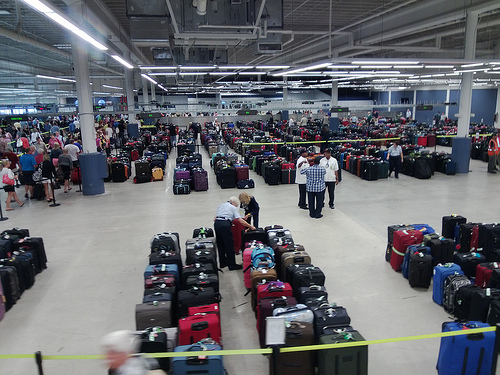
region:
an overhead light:
[108, 51, 133, 70]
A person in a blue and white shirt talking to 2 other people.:
[300, 155, 325, 216]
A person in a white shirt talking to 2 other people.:
[317, 148, 338, 208]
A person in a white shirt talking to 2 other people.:
[293, 147, 315, 209]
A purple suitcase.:
[192, 170, 209, 192]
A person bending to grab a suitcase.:
[213, 196, 255, 268]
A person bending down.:
[238, 192, 259, 228]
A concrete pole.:
[66, 1, 104, 195]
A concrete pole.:
[450, 12, 479, 173]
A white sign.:
[262, 315, 287, 374]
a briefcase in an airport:
[318, 324, 365, 374]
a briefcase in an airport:
[268, 318, 317, 368]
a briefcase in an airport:
[314, 302, 350, 324]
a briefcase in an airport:
[173, 344, 220, 372]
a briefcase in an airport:
[176, 310, 222, 357]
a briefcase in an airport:
[181, 284, 213, 304]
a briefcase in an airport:
[134, 297, 176, 332]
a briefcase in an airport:
[145, 291, 175, 302]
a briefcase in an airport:
[143, 260, 182, 277]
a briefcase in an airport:
[188, 269, 217, 283]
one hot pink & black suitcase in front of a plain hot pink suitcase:
[173, 298, 225, 347]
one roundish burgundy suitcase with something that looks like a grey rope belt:
[387, 228, 423, 272]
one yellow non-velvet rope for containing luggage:
[0, 317, 499, 374]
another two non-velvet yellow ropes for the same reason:
[237, 128, 494, 149]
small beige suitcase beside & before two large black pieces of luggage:
[133, 154, 166, 189]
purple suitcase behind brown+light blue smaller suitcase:
[170, 166, 195, 199]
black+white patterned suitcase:
[436, 270, 474, 319]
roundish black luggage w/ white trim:
[445, 283, 498, 327]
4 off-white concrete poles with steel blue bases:
[65, 1, 480, 198]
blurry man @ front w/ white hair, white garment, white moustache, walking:
[92, 324, 171, 374]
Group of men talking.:
[290, 143, 345, 216]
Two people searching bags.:
[205, 186, 271, 266]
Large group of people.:
[0, 107, 135, 214]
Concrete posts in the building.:
[58, 6, 497, 193]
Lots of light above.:
[13, 1, 497, 116]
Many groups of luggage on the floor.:
[5, 111, 496, 370]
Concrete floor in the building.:
[1, 114, 497, 369]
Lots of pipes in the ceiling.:
[1, 1, 494, 98]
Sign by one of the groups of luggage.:
[257, 317, 304, 374]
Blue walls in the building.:
[357, 91, 498, 126]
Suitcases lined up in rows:
[165, 122, 250, 190]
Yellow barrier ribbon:
[286, 315, 494, 366]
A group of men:
[293, 141, 347, 213]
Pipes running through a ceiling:
[162, 7, 334, 57]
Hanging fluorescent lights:
[50, 11, 138, 56]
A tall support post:
[453, 7, 480, 176]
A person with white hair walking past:
[102, 318, 171, 361]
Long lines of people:
[12, 89, 135, 186]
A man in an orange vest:
[480, 128, 499, 168]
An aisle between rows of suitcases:
[309, 223, 426, 343]